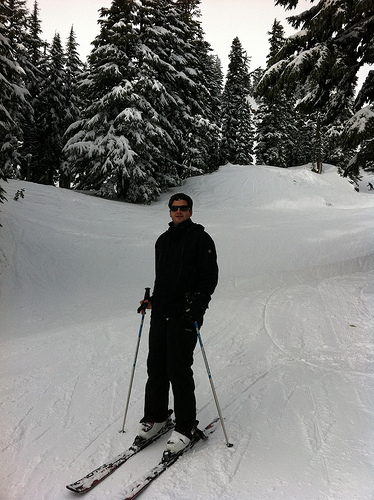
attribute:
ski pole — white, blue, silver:
[189, 316, 232, 446]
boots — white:
[136, 420, 189, 451]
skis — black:
[81, 461, 163, 488]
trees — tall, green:
[87, 12, 254, 179]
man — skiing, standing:
[103, 181, 205, 376]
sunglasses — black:
[161, 204, 214, 210]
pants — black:
[132, 311, 207, 415]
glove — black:
[193, 308, 213, 327]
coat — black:
[163, 234, 225, 307]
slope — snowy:
[229, 276, 308, 474]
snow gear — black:
[161, 231, 187, 395]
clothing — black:
[150, 237, 203, 416]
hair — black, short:
[171, 192, 188, 203]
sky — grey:
[57, 4, 357, 88]